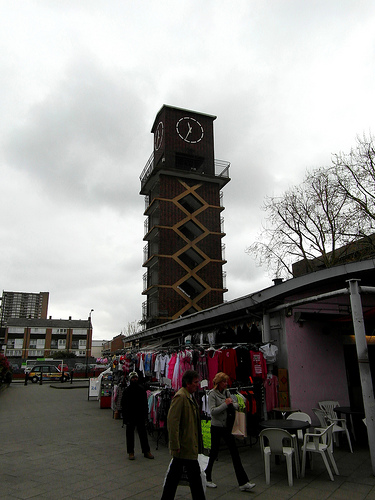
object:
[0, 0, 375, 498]
outdoor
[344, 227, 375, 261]
snowy branches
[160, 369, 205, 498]
man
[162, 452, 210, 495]
shopping bag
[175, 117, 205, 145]
clock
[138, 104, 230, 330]
tall tower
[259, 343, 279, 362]
dress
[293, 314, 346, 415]
wall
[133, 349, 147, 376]
clothing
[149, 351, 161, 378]
clothing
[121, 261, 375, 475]
building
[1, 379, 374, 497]
walk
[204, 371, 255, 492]
pedestrian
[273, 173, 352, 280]
tree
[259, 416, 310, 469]
table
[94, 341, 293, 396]
rack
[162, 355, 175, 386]
dress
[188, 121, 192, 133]
hour hand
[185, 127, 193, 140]
minute hand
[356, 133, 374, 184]
branches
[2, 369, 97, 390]
street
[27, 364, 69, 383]
car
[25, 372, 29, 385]
post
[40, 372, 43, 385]
post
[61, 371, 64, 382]
post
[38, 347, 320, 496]
ground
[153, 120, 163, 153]
clock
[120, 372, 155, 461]
man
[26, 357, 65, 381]
bush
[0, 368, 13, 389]
bush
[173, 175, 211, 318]
design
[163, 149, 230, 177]
railings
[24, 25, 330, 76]
sky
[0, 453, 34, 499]
bricks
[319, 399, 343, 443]
chair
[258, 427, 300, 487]
chair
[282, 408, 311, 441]
chair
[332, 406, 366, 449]
table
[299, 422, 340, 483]
chair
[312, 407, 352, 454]
chair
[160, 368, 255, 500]
couple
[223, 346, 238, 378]
clothing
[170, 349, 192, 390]
clothing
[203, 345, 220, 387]
clothing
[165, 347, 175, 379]
clothing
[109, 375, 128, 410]
clothing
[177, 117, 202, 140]
face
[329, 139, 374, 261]
tree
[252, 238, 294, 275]
branch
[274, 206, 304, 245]
branch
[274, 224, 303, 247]
branch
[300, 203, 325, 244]
branch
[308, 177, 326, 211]
branch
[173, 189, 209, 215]
section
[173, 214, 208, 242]
section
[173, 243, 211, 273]
section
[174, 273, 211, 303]
section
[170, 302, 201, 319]
section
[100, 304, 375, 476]
shopping area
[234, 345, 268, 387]
clothes